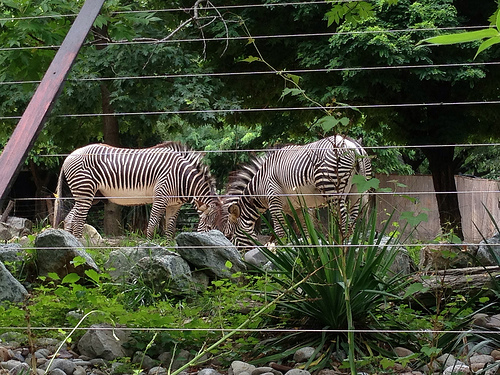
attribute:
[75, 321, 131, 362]
rock — dark gray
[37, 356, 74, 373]
rock — dark gray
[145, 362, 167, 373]
rock — dark gray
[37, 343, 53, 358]
rock — dark gray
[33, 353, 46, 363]
rock — dark gray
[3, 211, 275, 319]
rocks — large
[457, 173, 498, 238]
fence — wooden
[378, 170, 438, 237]
fence — wooden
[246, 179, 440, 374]
bush — green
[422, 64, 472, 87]
leaves — green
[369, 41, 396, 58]
leaves — green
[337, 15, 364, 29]
leaves — green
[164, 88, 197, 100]
leaves — green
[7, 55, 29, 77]
leaves — green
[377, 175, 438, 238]
wall — gray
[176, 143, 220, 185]
mane — black, white, striped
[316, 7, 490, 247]
tree — large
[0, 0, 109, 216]
post — discolored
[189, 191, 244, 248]
head — down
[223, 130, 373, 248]
zebra — striped